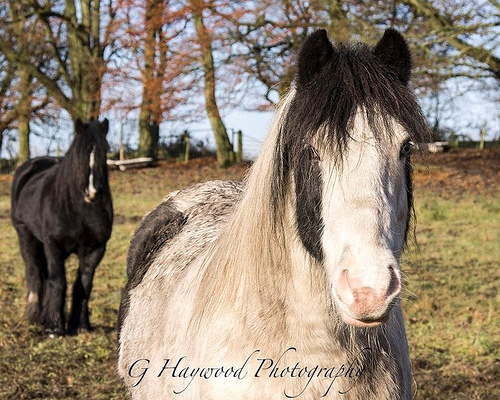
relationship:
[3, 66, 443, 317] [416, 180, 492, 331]
horses in field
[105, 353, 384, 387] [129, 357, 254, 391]
watermark of photographer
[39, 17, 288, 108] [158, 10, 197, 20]
trees losing leaves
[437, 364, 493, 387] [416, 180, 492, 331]
dry grass in field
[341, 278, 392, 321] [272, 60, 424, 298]
nose of horse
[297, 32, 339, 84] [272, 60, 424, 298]
ear of horse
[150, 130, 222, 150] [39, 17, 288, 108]
fence behind trees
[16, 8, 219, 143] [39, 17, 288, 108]
group of trees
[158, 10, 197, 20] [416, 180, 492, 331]
leaves on field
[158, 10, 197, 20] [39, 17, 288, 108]
leaves on trees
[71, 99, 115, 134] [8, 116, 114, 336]
ears of horses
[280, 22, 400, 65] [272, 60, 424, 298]
ears of horse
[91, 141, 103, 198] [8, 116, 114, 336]
markings on horses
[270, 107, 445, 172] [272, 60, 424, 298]
eyes of horse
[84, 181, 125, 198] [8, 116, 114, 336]
nose of horses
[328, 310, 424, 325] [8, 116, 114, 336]
mouth of horses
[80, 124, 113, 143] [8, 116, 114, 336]
mane on horses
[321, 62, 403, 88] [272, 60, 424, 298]
mane on horse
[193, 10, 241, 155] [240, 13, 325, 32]
tree with branch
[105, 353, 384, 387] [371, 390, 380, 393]
watermark on bottom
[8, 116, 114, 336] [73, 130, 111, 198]
horses has face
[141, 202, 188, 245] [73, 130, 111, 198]
markings on face